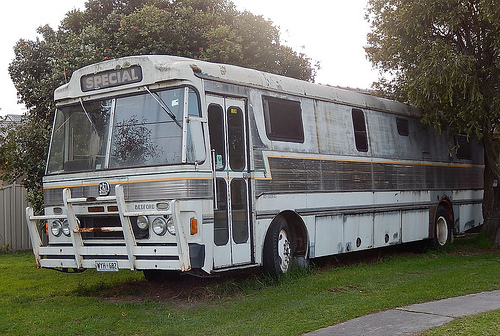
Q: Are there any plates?
A: Yes, there is a plate.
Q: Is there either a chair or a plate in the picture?
A: Yes, there is a plate.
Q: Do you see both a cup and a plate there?
A: No, there is a plate but no cups.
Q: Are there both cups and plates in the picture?
A: No, there is a plate but no cups.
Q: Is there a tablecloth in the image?
A: No, there are no tablecloths.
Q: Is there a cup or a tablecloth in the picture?
A: No, there are no tablecloths or cups.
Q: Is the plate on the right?
A: No, the plate is on the left of the image.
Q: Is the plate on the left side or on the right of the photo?
A: The plate is on the left of the image.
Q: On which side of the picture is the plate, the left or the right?
A: The plate is on the left of the image.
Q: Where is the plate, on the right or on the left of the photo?
A: The plate is on the left of the image.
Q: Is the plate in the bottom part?
A: Yes, the plate is in the bottom of the image.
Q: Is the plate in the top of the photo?
A: No, the plate is in the bottom of the image.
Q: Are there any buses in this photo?
A: Yes, there is a bus.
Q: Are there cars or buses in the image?
A: Yes, there is a bus.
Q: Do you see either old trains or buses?
A: Yes, there is an old bus.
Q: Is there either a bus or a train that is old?
A: Yes, the bus is old.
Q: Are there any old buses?
A: Yes, there is an old bus.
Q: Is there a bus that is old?
A: Yes, there is a bus that is old.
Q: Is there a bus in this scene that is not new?
A: Yes, there is a old bus.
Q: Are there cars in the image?
A: No, there are no cars.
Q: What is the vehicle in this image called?
A: The vehicle is a bus.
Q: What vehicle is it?
A: The vehicle is a bus.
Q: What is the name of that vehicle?
A: This is a bus.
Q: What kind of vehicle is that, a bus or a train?
A: This is a bus.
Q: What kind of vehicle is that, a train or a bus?
A: This is a bus.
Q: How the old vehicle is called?
A: The vehicle is a bus.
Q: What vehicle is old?
A: The vehicle is a bus.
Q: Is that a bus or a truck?
A: That is a bus.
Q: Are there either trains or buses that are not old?
A: No, there is a bus but it is old.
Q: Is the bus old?
A: Yes, the bus is old.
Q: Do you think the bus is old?
A: Yes, the bus is old.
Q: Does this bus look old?
A: Yes, the bus is old.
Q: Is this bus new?
A: No, the bus is old.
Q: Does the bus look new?
A: No, the bus is old.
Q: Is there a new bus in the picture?
A: No, there is a bus but it is old.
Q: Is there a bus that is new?
A: No, there is a bus but it is old.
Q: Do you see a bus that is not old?
A: No, there is a bus but it is old.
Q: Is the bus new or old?
A: The bus is old.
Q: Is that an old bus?
A: Yes, that is an old bus.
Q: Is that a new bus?
A: No, that is an old bus.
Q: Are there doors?
A: Yes, there is a door.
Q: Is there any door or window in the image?
A: Yes, there is a door.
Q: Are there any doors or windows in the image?
A: Yes, there is a door.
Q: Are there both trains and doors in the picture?
A: No, there is a door but no trains.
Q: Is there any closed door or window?
A: Yes, there is a closed door.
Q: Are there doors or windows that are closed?
A: Yes, the door is closed.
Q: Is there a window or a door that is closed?
A: Yes, the door is closed.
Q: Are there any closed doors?
A: Yes, there is a closed door.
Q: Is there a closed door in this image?
A: Yes, there is a closed door.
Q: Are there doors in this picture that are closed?
A: Yes, there is a door that is closed.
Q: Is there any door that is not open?
A: Yes, there is an closed door.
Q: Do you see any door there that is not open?
A: Yes, there is an closed door.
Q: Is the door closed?
A: Yes, the door is closed.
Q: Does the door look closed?
A: Yes, the door is closed.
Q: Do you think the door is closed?
A: Yes, the door is closed.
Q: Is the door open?
A: No, the door is closed.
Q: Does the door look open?
A: No, the door is closed.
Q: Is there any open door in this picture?
A: No, there is a door but it is closed.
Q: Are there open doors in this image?
A: No, there is a door but it is closed.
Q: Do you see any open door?
A: No, there is a door but it is closed.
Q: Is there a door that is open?
A: No, there is a door but it is closed.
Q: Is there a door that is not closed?
A: No, there is a door but it is closed.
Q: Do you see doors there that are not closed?
A: No, there is a door but it is closed.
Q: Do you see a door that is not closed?
A: No, there is a door but it is closed.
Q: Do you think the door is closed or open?
A: The door is closed.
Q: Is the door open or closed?
A: The door is closed.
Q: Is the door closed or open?
A: The door is closed.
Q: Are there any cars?
A: No, there are no cars.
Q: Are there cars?
A: No, there are no cars.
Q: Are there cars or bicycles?
A: No, there are no cars or bicycles.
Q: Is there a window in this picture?
A: Yes, there are windows.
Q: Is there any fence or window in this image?
A: Yes, there are windows.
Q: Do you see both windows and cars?
A: No, there are windows but no cars.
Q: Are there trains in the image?
A: No, there are no trains.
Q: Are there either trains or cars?
A: No, there are no trains or cars.